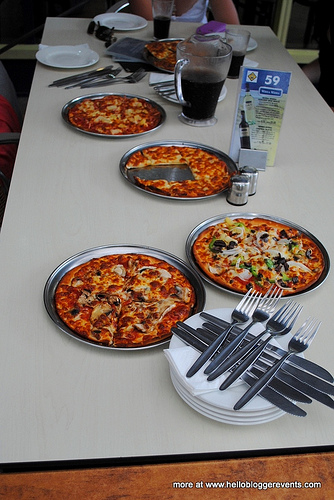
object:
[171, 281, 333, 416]
forks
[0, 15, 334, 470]
table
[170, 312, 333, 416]
knives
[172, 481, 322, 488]
letters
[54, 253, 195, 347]
pizza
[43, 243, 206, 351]
pan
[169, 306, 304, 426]
white plates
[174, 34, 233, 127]
pitcher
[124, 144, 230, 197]
pizza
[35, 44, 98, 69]
plate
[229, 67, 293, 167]
menu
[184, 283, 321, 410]
metal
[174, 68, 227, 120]
juice